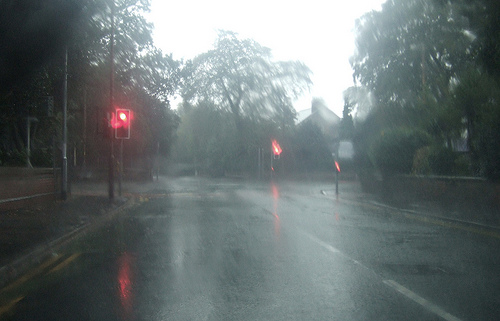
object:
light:
[116, 252, 134, 303]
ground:
[0, 178, 500, 319]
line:
[299, 227, 463, 321]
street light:
[271, 140, 283, 155]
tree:
[173, 29, 315, 175]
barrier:
[378, 178, 447, 203]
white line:
[274, 196, 452, 318]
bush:
[369, 127, 500, 178]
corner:
[54, 194, 136, 232]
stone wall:
[364, 165, 499, 219]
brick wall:
[0, 167, 59, 211]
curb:
[9, 197, 139, 302]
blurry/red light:
[111, 108, 131, 130]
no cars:
[0, 159, 470, 319]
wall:
[381, 182, 444, 201]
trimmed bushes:
[409, 144, 453, 175]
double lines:
[2, 253, 76, 319]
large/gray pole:
[56, 40, 70, 204]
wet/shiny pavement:
[144, 179, 252, 319]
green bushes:
[369, 125, 427, 173]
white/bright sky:
[153, 0, 355, 51]